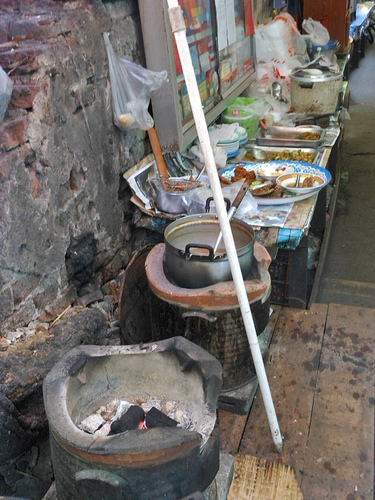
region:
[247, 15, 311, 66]
a bag of disposable plates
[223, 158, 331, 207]
a large white and blue platter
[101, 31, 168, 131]
a plastic bag hanging from wall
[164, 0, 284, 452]
a long white metal pole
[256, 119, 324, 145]
a square boil pan of food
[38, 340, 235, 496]
a dented fireplace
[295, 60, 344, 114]
a large aluminum pot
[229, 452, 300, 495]
a section of wood grain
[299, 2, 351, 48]
a brown wooden cabinet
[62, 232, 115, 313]
a break in the wall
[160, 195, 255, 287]
a pot with two handles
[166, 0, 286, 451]
a long white stick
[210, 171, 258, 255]
a ladle in a pot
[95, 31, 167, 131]
a hanging clear plastic bag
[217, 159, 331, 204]
a large blue and white platter full of food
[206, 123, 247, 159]
round blue and white dishes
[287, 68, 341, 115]
a large pot with a lid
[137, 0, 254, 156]
a glass encased bulletin board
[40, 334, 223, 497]
a fire pit filled with ashes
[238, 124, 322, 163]
two rectangular metal pans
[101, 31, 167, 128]
A clear plastic bag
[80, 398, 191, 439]
Ashes in the bucket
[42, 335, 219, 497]
Bucket made of cement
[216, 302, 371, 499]
Floor made of wood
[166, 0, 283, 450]
A long white pole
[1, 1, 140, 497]
Wall made of bricks and cement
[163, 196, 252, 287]
A round metal pot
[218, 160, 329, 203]
Food in a large bowl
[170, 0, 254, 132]
Papers in a display case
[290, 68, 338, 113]
The crock pot is dirty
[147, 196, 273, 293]
the pot is silver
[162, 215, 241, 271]
the pot is silver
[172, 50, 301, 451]
the pole is white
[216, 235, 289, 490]
the pole is white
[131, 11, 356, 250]
food set up on a sidewalk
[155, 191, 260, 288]
pot set upon another pot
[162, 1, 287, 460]
white stick leaning up against the wall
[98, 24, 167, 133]
plastic bag hanging on the wall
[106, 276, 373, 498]
wooden planks on the ground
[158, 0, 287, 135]
bulletin board against the wall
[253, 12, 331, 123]
bunch of plastic bags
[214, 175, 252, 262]
long spoon in a pot of soup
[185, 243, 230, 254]
soup in a big pot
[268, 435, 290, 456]
pointed end of a white stick